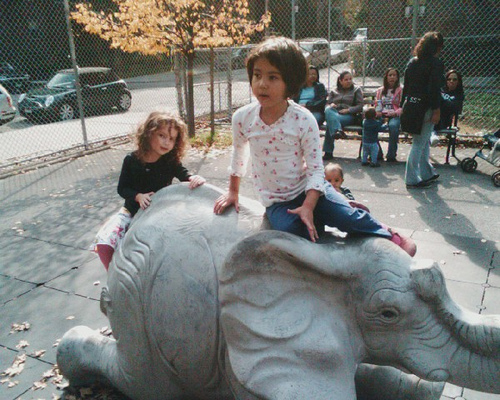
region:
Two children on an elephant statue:
[56, 34, 498, 399]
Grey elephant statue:
[52, 178, 496, 398]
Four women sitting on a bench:
[300, 65, 464, 165]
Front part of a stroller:
[460, 120, 497, 187]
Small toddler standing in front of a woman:
[356, 65, 406, 169]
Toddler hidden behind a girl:
[321, 163, 353, 200]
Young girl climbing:
[89, 108, 207, 275]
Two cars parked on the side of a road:
[1, 64, 133, 124]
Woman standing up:
[395, 30, 451, 192]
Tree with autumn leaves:
[72, 1, 274, 138]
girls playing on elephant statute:
[97, 48, 430, 254]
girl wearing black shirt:
[86, 110, 192, 257]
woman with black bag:
[388, 24, 444, 186]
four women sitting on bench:
[304, 59, 459, 162]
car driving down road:
[19, 70, 132, 115]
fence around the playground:
[13, 4, 493, 121]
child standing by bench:
[358, 103, 389, 161]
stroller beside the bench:
[460, 120, 498, 178]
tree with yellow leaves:
[77, 1, 259, 128]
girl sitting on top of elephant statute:
[205, 24, 405, 247]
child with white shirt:
[211, 38, 425, 254]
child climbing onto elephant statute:
[83, 112, 193, 259]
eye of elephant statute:
[372, 306, 399, 326]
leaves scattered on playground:
[15, 187, 465, 398]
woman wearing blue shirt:
[289, 65, 320, 106]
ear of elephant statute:
[216, 237, 366, 397]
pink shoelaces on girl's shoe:
[389, 229, 414, 255]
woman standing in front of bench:
[391, 32, 451, 187]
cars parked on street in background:
[271, 27, 374, 72]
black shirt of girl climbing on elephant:
[117, 155, 195, 202]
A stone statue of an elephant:
[54, 180, 499, 397]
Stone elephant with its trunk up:
[403, 256, 499, 391]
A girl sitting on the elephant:
[211, 35, 418, 257]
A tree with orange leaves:
[68, 0, 276, 141]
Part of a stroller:
[459, 128, 499, 188]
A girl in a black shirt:
[116, 148, 193, 214]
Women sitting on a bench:
[294, 65, 464, 166]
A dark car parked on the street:
[18, 64, 131, 125]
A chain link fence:
[0, 0, 499, 180]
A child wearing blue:
[358, 105, 390, 167]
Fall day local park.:
[86, 44, 484, 390]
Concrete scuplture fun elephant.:
[62, 177, 499, 398]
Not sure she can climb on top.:
[93, 105, 207, 271]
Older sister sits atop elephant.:
[222, 29, 325, 299]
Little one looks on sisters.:
[310, 155, 365, 228]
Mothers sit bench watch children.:
[295, 32, 497, 192]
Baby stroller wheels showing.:
[447, 116, 499, 185]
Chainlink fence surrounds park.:
[2, 29, 119, 189]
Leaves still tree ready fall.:
[69, 2, 251, 141]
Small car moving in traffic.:
[19, 58, 141, 118]